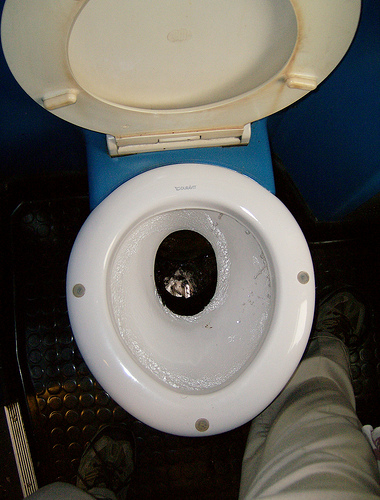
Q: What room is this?
A: Bathroom.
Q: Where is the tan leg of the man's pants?
A: Beside the toilet.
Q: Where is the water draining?
A: Into the hole.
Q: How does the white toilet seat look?
A: Sitting up.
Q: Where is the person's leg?
A: In the bathroom.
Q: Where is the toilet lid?
A: In a bathroom stall.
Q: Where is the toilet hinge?
A: Bottom of lid.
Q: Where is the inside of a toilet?
A: In a bathroom stall.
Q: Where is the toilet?
A: In a bathroom.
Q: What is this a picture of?
A: Toilet.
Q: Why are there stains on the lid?
A: Lid is old.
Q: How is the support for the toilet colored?
A: Blue.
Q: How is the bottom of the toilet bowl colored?
A: Black.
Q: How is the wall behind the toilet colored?
A: Blue.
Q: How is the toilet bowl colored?
A: White.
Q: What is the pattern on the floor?
A: Round dots.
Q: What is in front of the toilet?
A: Legs.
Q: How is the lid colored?
A: White with stains.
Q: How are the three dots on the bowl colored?
A: Grey.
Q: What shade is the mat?
A: Black.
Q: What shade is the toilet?
A: White.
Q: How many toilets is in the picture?
A: One.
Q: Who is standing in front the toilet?
A: A man.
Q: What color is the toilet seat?
A: Yellowish.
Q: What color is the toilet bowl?
A: White.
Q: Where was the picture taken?
A: In the bathroom.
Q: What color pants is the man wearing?
A: Beige.